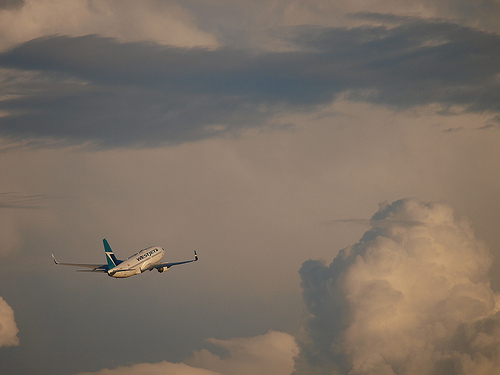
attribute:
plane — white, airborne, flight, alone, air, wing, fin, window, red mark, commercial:
[36, 226, 255, 314]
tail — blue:
[86, 238, 127, 265]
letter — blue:
[144, 242, 162, 260]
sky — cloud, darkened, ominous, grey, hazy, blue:
[155, 100, 280, 157]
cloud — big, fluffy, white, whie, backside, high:
[352, 214, 428, 283]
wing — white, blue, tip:
[159, 253, 201, 285]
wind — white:
[208, 299, 245, 325]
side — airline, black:
[50, 201, 194, 306]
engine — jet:
[162, 263, 181, 281]